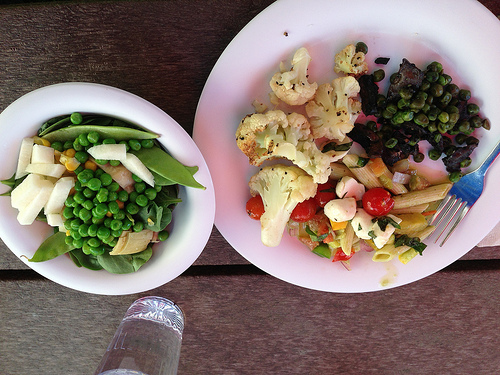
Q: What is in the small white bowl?
A: Green and white vegetables.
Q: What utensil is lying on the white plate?
A: Fork.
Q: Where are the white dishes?
A: On a table.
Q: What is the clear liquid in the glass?
A: Water.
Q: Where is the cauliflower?
A: On the white plate.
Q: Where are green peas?
A: In the small bowl.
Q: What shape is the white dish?
A: Round.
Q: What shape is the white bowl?
A: Round.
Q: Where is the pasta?
A: Next to the fork.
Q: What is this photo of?
A: Two plates of food.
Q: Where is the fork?
A: On the large white plate.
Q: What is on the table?
A: Plate and bowl.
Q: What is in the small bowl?
A: Veggies.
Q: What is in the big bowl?
A: More veggies.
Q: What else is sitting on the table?
A: Drinking glass.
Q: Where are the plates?
A: On a table.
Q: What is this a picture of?
A: A meal.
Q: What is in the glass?
A: Water.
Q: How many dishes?
A: Two.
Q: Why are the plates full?
A: The person hasn't eaten yet.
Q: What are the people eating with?
A: A fork.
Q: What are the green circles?
A: Peas.